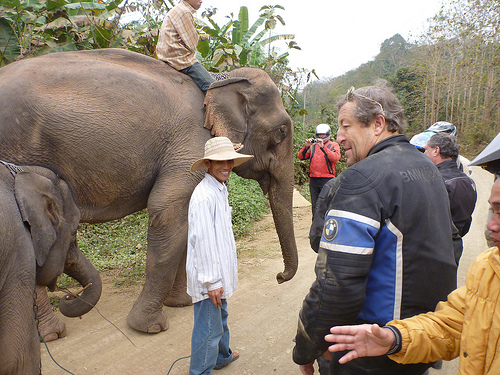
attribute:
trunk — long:
[259, 156, 320, 304]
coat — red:
[297, 135, 344, 178]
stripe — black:
[304, 140, 316, 175]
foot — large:
[124, 282, 174, 338]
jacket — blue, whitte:
[285, 142, 455, 304]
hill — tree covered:
[301, 39, 400, 111]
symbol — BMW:
[323, 217, 339, 242]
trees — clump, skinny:
[361, 1, 493, 124]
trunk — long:
[230, 128, 324, 305]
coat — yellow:
[388, 246, 498, 374]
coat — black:
[330, 82, 437, 344]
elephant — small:
[3, 142, 113, 373]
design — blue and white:
[312, 195, 422, 293]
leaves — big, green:
[48, 0, 157, 56]